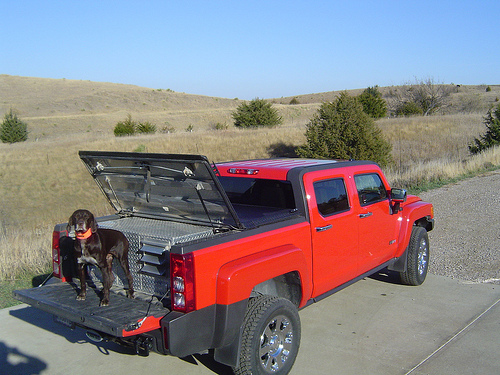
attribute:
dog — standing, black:
[67, 213, 136, 298]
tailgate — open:
[13, 280, 169, 341]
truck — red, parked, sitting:
[23, 152, 435, 373]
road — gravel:
[365, 174, 483, 374]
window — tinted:
[219, 174, 299, 214]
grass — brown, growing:
[55, 95, 101, 144]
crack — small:
[403, 295, 495, 369]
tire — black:
[242, 294, 300, 374]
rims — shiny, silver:
[260, 315, 295, 371]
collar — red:
[71, 229, 96, 240]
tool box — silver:
[103, 218, 210, 300]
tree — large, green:
[309, 94, 388, 161]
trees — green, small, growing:
[237, 85, 394, 165]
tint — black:
[230, 181, 264, 194]